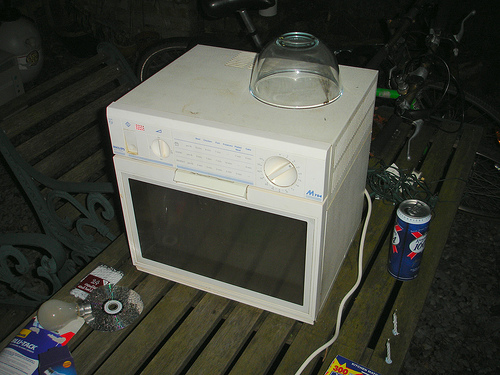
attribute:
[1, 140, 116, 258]
arm rest — metal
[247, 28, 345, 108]
bowl — down, glassy, inverted, glass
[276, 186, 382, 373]
cord — long, white, electrical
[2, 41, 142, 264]
chair — metal, wooden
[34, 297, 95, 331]
light bulb — white, glassy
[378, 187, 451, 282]
can — blue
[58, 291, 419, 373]
table — brown, wooden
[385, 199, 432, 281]
can — blue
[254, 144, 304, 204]
knob —  adjusting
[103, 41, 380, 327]
microwave oven — white,  microwave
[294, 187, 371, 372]
cord —  for power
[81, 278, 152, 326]
disk — compact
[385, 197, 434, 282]
beverage — tall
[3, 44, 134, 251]
bench — wood, old, iron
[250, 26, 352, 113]
glass —  clear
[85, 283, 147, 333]
compact disc —  without case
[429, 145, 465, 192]
bench — wooden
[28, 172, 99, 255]
armrest — wrought iron, ornamental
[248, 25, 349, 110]
bowl — clear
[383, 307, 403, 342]
candle — white, wax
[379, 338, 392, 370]
candle — white, wax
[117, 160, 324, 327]
oven door — closed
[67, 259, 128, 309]
cigarette pack — maroon, white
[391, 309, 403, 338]
candle — white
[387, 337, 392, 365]
candle — white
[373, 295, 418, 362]
rope — white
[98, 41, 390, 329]
microwave — white 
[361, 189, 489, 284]
can — beer, open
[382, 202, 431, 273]
can — red, white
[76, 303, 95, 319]
base — silver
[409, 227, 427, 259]
design — white, red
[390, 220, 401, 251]
design — red, white